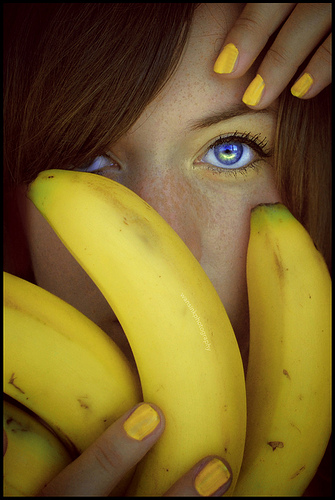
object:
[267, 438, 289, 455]
spot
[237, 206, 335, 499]
banana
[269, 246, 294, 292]
line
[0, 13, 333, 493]
girl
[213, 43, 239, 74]
fingernail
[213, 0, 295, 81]
finger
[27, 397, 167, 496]
finger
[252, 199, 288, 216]
tip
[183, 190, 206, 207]
freckle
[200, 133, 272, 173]
eye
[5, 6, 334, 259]
hair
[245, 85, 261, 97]
polish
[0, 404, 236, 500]
hand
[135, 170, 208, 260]
nose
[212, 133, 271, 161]
eyelash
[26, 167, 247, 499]
banana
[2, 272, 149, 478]
banana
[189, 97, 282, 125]
eyebrow